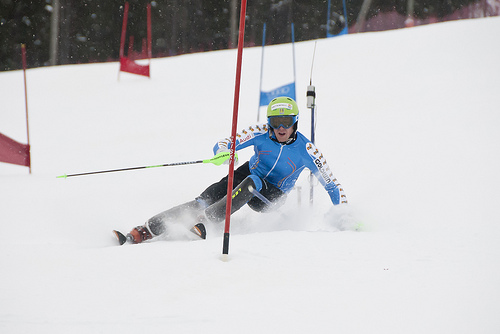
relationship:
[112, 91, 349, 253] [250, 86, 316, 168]
man wearing helmet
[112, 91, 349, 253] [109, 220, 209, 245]
man on skis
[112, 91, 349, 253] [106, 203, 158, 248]
man on skiis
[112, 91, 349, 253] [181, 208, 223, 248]
man on skiis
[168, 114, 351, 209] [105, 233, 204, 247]
man riding skis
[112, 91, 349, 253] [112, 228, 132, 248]
man riding ski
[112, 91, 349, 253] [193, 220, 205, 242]
man riding ski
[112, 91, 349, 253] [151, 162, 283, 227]
man wearing pants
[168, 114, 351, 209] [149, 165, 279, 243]
man wearing pants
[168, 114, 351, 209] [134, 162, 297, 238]
man wearing pants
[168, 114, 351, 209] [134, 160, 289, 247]
man wearing black pants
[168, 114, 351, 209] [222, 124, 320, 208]
man wearing jacket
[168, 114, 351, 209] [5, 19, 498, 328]
man on hill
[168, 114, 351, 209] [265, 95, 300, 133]
man wearing helmet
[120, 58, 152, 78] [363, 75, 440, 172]
sign on snow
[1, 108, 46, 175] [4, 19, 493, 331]
sign on snow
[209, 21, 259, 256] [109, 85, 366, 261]
pole in front of skier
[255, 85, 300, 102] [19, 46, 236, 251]
flag on course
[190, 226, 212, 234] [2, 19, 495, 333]
ski on ground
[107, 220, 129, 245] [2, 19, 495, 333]
ski on ground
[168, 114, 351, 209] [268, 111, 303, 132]
man wearing goggles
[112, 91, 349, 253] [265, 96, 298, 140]
man has head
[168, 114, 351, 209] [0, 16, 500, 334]
man on ground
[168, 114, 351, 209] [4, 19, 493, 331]
man skiing on snow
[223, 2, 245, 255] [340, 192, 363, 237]
skipole on hand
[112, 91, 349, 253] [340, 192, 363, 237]
man has hand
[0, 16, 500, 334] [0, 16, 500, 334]
ground between ground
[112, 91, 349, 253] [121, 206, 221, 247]
man wearing ski shoes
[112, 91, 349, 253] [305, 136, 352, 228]
man wears sleeve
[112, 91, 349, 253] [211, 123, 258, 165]
man wears sleeve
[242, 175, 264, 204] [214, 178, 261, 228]
band in knee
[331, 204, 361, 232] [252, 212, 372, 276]
hand are in snow